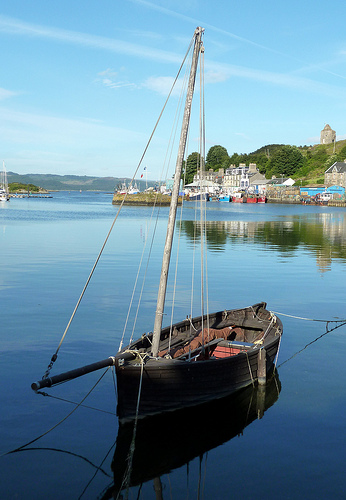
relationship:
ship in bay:
[30, 20, 282, 427] [0, 194, 345, 499]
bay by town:
[0, 194, 345, 499] [179, 159, 269, 202]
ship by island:
[30, 20, 282, 427] [112, 183, 183, 207]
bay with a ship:
[0, 194, 345, 499] [30, 20, 282, 427]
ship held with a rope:
[30, 20, 282, 427] [268, 307, 345, 326]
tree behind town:
[203, 143, 228, 170] [179, 159, 269, 202]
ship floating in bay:
[30, 20, 282, 427] [0, 194, 345, 499]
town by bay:
[179, 159, 269, 202] [0, 194, 345, 499]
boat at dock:
[216, 191, 230, 203] [184, 192, 218, 203]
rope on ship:
[268, 307, 345, 326] [30, 20, 282, 427]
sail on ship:
[161, 324, 234, 360] [30, 20, 282, 427]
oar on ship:
[173, 335, 224, 362] [30, 20, 282, 427]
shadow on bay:
[111, 371, 287, 486] [0, 194, 345, 499]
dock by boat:
[184, 192, 218, 203] [216, 191, 230, 203]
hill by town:
[208, 140, 342, 178] [179, 159, 269, 202]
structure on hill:
[317, 123, 338, 147] [208, 140, 342, 178]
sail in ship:
[161, 324, 234, 360] [30, 20, 282, 427]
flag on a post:
[136, 164, 148, 181] [142, 166, 150, 190]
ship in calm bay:
[30, 20, 282, 427] [0, 194, 345, 499]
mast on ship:
[149, 26, 203, 357] [30, 20, 282, 427]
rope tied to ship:
[268, 307, 345, 326] [30, 20, 282, 427]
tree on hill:
[203, 143, 228, 170] [208, 140, 342, 178]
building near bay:
[300, 183, 345, 198] [0, 194, 345, 499]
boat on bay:
[216, 191, 230, 203] [0, 194, 345, 499]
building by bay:
[300, 183, 345, 198] [0, 194, 345, 499]